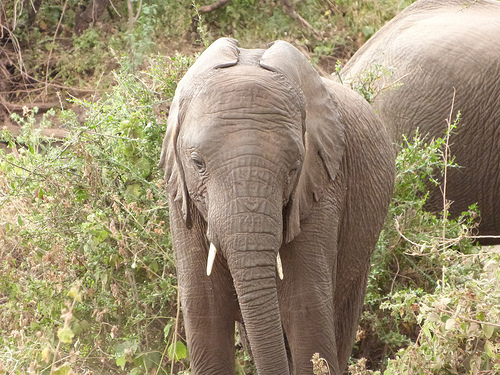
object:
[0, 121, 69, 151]
branch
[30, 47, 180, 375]
bushes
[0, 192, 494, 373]
ground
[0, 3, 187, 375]
grass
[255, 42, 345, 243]
ear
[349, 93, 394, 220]
skin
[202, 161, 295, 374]
trunk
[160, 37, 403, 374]
elephant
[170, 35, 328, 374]
head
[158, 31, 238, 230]
ear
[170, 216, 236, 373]
leg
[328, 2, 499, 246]
elephant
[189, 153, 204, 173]
eye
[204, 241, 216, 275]
tusk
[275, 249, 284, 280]
tusk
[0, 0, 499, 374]
area